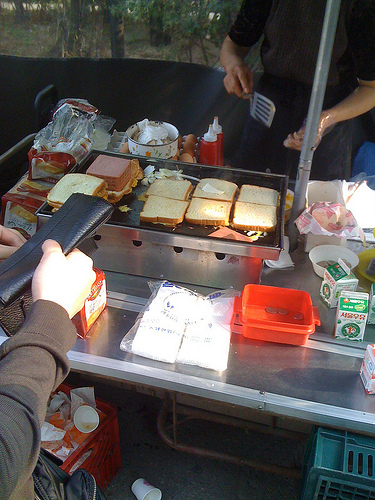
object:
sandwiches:
[139, 194, 190, 225]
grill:
[33, 146, 291, 295]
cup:
[129, 475, 164, 499]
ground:
[69, 381, 306, 500]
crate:
[38, 381, 123, 497]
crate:
[299, 423, 375, 500]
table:
[0, 130, 375, 437]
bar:
[156, 393, 304, 478]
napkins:
[204, 320, 212, 347]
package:
[118, 277, 241, 374]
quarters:
[277, 309, 288, 315]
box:
[233, 282, 321, 348]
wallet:
[0, 190, 116, 308]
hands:
[29, 234, 98, 319]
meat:
[84, 154, 132, 193]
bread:
[139, 194, 190, 228]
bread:
[231, 200, 279, 233]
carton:
[333, 288, 370, 342]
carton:
[318, 256, 361, 311]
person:
[0, 220, 98, 499]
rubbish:
[39, 385, 98, 472]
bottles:
[198, 123, 218, 166]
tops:
[203, 122, 217, 143]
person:
[217, 0, 375, 184]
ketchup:
[203, 147, 213, 159]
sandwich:
[232, 182, 281, 233]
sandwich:
[45, 171, 110, 208]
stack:
[84, 152, 145, 203]